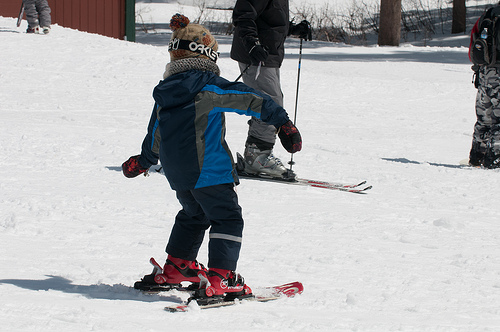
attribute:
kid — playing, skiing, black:
[128, 7, 284, 303]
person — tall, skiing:
[224, 5, 341, 195]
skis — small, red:
[135, 257, 310, 322]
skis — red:
[161, 270, 303, 312]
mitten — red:
[120, 150, 152, 179]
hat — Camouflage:
[154, 20, 216, 60]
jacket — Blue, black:
[135, 79, 256, 190]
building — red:
[50, 2, 140, 41]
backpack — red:
[465, 12, 484, 62]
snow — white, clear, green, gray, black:
[2, 2, 484, 330]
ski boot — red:
[162, 251, 209, 284]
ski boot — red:
[205, 266, 253, 299]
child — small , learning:
[119, 12, 302, 300]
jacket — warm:
[138, 68, 288, 190]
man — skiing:
[229, 1, 314, 182]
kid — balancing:
[120, 11, 303, 296]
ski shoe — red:
[162, 250, 209, 281]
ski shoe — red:
[204, 265, 252, 300]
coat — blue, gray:
[138, 68, 288, 190]